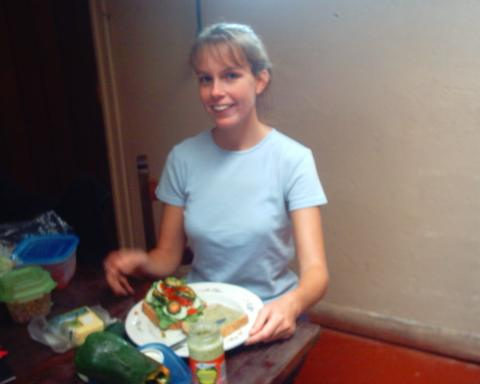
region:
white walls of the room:
[343, 37, 459, 215]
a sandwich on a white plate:
[148, 279, 251, 340]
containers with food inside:
[1, 227, 88, 327]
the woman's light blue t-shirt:
[147, 134, 342, 283]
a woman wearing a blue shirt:
[114, 21, 357, 307]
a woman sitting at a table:
[86, 66, 367, 375]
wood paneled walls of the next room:
[16, 35, 90, 165]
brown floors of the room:
[323, 337, 412, 380]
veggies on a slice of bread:
[142, 275, 205, 320]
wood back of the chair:
[122, 149, 177, 255]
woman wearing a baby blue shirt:
[155, 125, 329, 331]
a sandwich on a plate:
[141, 273, 247, 342]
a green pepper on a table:
[79, 332, 172, 382]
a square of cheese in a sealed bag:
[29, 300, 118, 354]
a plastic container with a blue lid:
[12, 236, 79, 286]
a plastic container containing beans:
[1, 264, 57, 325]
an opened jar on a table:
[187, 326, 224, 382]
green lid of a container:
[1, 261, 59, 303]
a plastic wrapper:
[2, 210, 77, 248]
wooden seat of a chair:
[135, 155, 193, 279]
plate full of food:
[111, 268, 265, 366]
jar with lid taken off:
[181, 319, 227, 383]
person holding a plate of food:
[93, 10, 352, 360]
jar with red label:
[183, 319, 233, 383]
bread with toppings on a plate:
[139, 267, 208, 335]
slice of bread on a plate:
[177, 295, 251, 344]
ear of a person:
[250, 62, 272, 99]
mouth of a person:
[206, 98, 236, 117]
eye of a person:
[221, 67, 246, 82]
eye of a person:
[196, 71, 217, 88]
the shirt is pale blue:
[210, 170, 262, 213]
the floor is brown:
[337, 349, 382, 372]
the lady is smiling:
[192, 39, 262, 136]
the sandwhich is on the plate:
[151, 281, 245, 344]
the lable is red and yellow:
[193, 360, 216, 382]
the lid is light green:
[14, 274, 35, 291]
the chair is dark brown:
[125, 146, 159, 208]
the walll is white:
[354, 159, 409, 218]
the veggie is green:
[95, 336, 129, 373]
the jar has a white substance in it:
[193, 339, 219, 358]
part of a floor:
[346, 343, 362, 367]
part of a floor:
[344, 337, 365, 375]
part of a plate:
[234, 320, 249, 344]